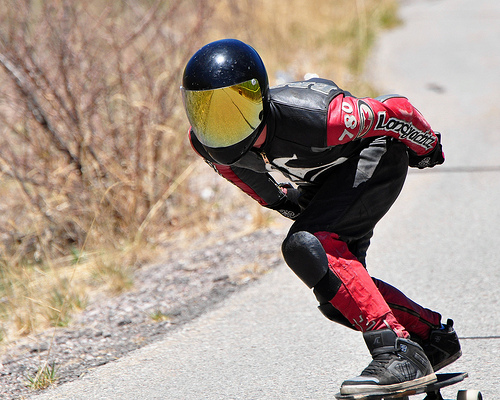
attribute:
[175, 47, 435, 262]
man — skating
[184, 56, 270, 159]
helmet — black, green, clear, yellow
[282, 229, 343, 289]
knee pads — black, blaack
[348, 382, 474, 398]
skateboard — black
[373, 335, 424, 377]
shoes — black